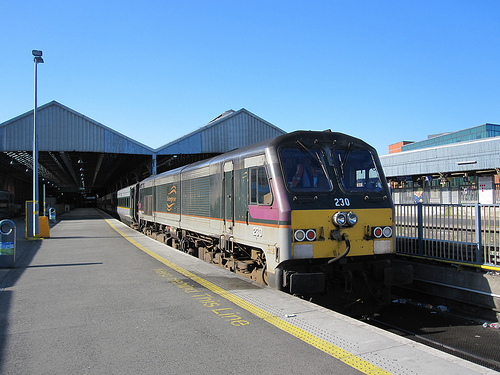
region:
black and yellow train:
[154, 141, 382, 269]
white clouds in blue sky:
[43, 14, 98, 58]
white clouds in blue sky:
[67, 52, 119, 110]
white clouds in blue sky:
[110, 17, 144, 47]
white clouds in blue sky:
[86, 30, 135, 90]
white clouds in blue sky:
[118, 68, 175, 131]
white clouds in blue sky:
[138, 17, 195, 61]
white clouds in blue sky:
[211, 21, 264, 63]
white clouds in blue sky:
[299, 22, 368, 96]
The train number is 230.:
[332, 195, 350, 205]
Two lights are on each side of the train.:
[291, 221, 391, 238]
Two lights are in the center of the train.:
[330, 210, 355, 225]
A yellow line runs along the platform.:
[86, 201, 391, 371]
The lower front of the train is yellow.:
[285, 205, 395, 255]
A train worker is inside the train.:
[285, 150, 320, 190]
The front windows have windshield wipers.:
[276, 138, 382, 197]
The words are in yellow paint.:
[150, 263, 252, 329]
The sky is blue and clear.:
[0, 0, 499, 155]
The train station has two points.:
[1, 98, 293, 150]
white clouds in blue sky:
[13, 7, 60, 29]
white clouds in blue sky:
[78, 50, 144, 103]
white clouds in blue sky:
[186, 57, 259, 93]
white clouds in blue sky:
[253, 16, 348, 66]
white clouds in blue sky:
[281, 54, 344, 111]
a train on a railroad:
[88, 111, 418, 313]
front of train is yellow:
[275, 138, 405, 276]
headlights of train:
[328, 202, 363, 237]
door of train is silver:
[212, 155, 242, 245]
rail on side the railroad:
[398, 192, 498, 282]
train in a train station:
[0, 71, 498, 361]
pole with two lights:
[25, 36, 46, 247]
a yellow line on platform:
[84, 209, 359, 373]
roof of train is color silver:
[107, 123, 337, 185]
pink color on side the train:
[234, 153, 294, 244]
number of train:
[333, 197, 350, 207]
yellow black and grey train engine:
[136, 128, 404, 296]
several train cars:
[94, 186, 137, 223]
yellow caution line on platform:
[102, 218, 390, 373]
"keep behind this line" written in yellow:
[148, 264, 251, 326]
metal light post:
[29, 49, 50, 238]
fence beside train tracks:
[395, 203, 495, 264]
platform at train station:
[3, 208, 498, 373]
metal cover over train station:
[0, 101, 289, 219]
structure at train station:
[373, 124, 499, 217]